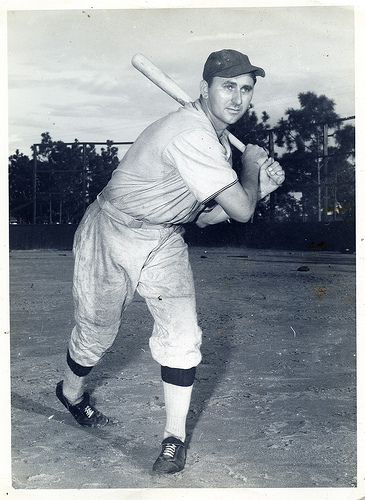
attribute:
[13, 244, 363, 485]
ground — cracked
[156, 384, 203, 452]
sock — long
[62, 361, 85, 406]
sock — long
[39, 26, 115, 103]
sky — cloudy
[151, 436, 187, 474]
shoe — black